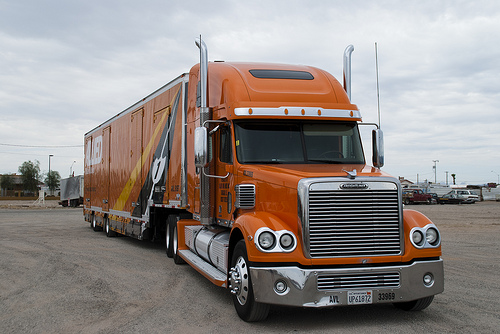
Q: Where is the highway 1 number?
A: On the side of the trailer.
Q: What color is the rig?
A: Orange.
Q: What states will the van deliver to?
A: All states except in Hawaii.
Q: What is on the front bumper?
A: A license plate.